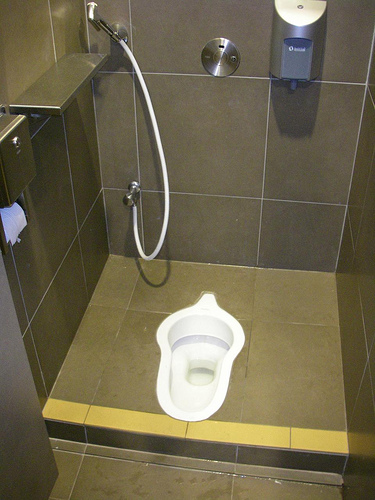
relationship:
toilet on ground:
[141, 275, 244, 433] [105, 261, 289, 499]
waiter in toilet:
[183, 346, 199, 398] [141, 275, 244, 433]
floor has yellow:
[105, 261, 289, 499] [242, 416, 284, 455]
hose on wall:
[95, 39, 182, 265] [62, 1, 267, 269]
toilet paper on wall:
[3, 132, 43, 247] [62, 1, 267, 269]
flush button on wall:
[197, 34, 247, 90] [62, 1, 267, 269]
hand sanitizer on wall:
[267, 2, 333, 112] [62, 1, 267, 269]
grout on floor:
[237, 468, 284, 486] [68, 456, 304, 497]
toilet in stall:
[141, 275, 244, 433] [62, 1, 348, 442]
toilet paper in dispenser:
[3, 132, 43, 247] [0, 112, 66, 249]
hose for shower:
[95, 39, 182, 265] [62, 1, 348, 442]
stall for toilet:
[62, 1, 348, 442] [141, 275, 244, 433]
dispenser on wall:
[0, 112, 66, 249] [62, 1, 267, 269]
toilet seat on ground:
[141, 275, 244, 433] [105, 261, 289, 499]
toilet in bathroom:
[141, 275, 244, 433] [57, 178, 365, 478]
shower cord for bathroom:
[106, 114, 201, 282] [57, 178, 365, 478]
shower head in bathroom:
[79, 0, 120, 22] [57, 178, 365, 478]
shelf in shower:
[26, 45, 117, 129] [62, 1, 348, 442]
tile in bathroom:
[246, 357, 347, 424] [57, 178, 365, 478]